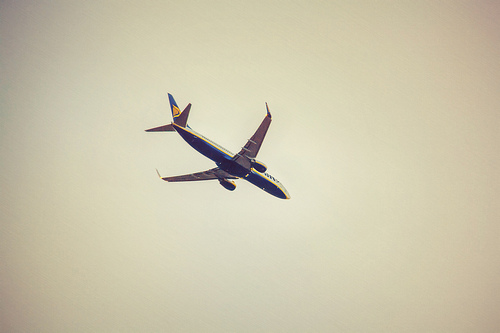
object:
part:
[245, 278, 284, 303]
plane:
[241, 170, 294, 206]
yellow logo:
[173, 108, 180, 117]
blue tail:
[166, 90, 180, 119]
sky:
[294, 0, 497, 33]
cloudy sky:
[338, 125, 406, 163]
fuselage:
[183, 133, 275, 187]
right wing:
[231, 98, 273, 174]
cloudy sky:
[367, 281, 497, 332]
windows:
[264, 170, 281, 182]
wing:
[158, 159, 238, 186]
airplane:
[145, 93, 288, 199]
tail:
[145, 92, 192, 135]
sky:
[428, 174, 468, 197]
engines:
[221, 159, 268, 191]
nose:
[277, 187, 289, 203]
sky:
[459, 236, 499, 264]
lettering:
[169, 103, 182, 115]